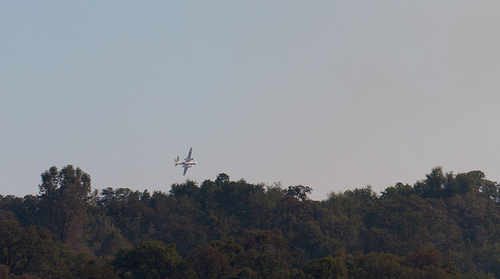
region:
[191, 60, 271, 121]
blue clear skies overhead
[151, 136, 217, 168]
white plane in the sky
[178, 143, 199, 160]
wings on the plane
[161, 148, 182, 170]
tail on the plane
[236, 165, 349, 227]
top of tall trees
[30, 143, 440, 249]
forest of green trees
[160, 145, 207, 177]
this is a plane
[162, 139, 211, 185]
the plane is side ways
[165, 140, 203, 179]
the plane is white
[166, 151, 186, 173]
tail of the plane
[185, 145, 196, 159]
left wing of plane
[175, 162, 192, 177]
right wing on plane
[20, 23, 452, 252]
the plane is flying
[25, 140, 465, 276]
multiple trees in the distance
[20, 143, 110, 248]
brown tree sticking outq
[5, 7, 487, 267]
the sky void of clouds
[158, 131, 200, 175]
plane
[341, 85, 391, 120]
white clouds in blue sky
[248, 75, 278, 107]
white clouds in blue sky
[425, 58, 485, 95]
white clouds in blue sky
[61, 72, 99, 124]
white clouds in blue sky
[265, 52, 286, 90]
white clouds in blue sky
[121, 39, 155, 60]
white clouds in blue sky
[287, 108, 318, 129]
white clouds in blue sky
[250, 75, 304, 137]
white clouds in blue sky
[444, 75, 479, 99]
white clouds in blue sky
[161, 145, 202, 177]
white plane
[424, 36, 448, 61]
white clouds in blue sky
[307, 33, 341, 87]
white clouds in blue sky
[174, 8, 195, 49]
white clouds in blue sky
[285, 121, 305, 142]
white clouds in blue sky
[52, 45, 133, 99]
white clouds in blue sky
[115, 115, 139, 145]
white clouds in blue sky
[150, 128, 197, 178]
plane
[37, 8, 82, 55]
white clouds in blue sky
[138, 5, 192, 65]
white clouds in blue sky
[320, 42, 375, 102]
white clouds in blue sky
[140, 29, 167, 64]
white clouds in blue sky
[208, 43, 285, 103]
white clouds in blue sky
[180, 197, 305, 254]
Trees growing in the background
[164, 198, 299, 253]
Trees in the forest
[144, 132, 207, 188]
A plane flying low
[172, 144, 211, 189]
A plane in the air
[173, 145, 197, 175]
the airplane has wings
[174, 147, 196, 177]
the airplane is flying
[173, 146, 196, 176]
the airplane is mid air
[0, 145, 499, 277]
the trees under the airplane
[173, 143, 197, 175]
the plane is on the air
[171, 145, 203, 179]
the airplane is flying high